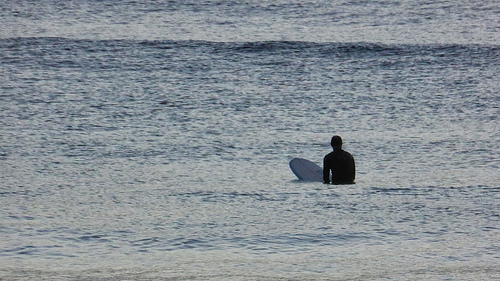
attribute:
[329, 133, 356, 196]
man — wet, sitting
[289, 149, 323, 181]
board — white, wet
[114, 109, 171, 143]
ocean — gray, large, wet, dark, moving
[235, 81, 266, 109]
water — dark